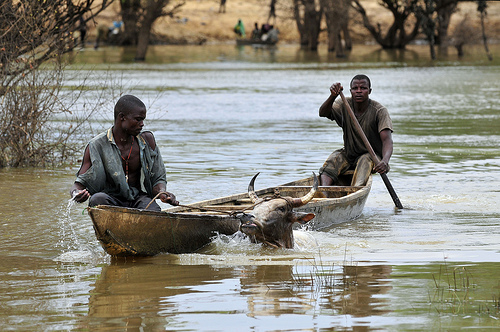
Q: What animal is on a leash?
A: Cow.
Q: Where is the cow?
A: Water.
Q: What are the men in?
A: Boat.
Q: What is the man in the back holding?
A: Oar.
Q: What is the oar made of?
A: Wood.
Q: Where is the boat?
A: In water.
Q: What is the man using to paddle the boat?
A: Oar.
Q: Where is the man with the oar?
A: Back of the boat.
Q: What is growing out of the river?
A: Trees.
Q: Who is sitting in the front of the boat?
A: A man wearing torn clothes.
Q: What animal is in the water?
A: A steer.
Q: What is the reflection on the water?
A: Men on a boat.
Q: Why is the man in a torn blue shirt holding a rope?
A: To guide the steer across the waterway.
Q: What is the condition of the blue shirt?
A: Torn and dirty.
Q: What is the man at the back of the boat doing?
A: Paddling.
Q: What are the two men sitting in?
A: A boat on the water.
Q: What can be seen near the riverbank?
A: People in another boat.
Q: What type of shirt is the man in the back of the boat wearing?
A: T Shirt.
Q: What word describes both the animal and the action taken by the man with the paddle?
A: Steer.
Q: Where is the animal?
A: In the water.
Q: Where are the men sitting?
A: On a rowboat.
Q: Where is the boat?
A: On the river.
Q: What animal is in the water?
A: A bull.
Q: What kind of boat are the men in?
A: A row boat.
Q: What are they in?
A: A canoe.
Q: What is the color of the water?
A: Brown.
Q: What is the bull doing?
A: Swimming.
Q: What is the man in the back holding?
A: A paddle.